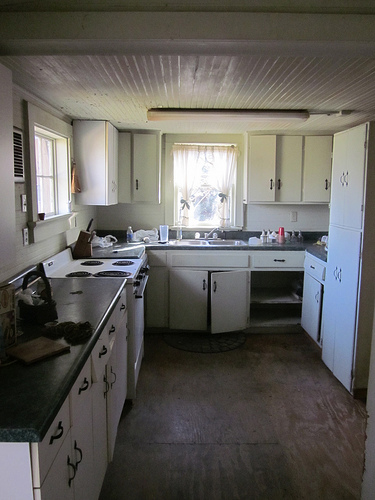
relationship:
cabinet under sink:
[209, 269, 248, 335] [163, 236, 246, 249]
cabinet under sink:
[168, 266, 209, 332] [163, 236, 246, 249]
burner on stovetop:
[77, 257, 103, 267] [44, 245, 145, 281]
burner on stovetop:
[111, 257, 134, 267] [44, 245, 145, 281]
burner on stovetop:
[63, 270, 89, 278] [44, 245, 145, 281]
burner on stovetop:
[95, 270, 130, 278] [44, 245, 145, 281]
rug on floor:
[155, 334, 247, 359] [98, 327, 374, 498]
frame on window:
[159, 135, 241, 230] [176, 143, 231, 227]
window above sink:
[176, 143, 231, 227] [170, 237, 247, 248]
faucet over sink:
[202, 225, 226, 239] [208, 238, 237, 249]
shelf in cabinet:
[252, 289, 303, 311] [249, 264, 305, 327]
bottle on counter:
[126, 226, 133, 243] [88, 234, 147, 259]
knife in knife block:
[85, 216, 93, 232] [73, 229, 95, 257]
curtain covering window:
[170, 144, 240, 229] [169, 138, 242, 232]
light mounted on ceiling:
[145, 107, 310, 126] [20, 57, 364, 139]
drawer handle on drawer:
[274, 258, 286, 263] [252, 248, 303, 269]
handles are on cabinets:
[267, 177, 285, 192] [243, 130, 341, 207]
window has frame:
[35, 124, 65, 216] [21, 97, 76, 141]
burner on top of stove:
[65, 270, 90, 278] [42, 244, 149, 406]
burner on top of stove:
[81, 260, 103, 266] [42, 244, 149, 406]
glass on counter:
[158, 222, 170, 242] [117, 236, 271, 250]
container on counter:
[275, 225, 286, 245] [237, 237, 310, 251]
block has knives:
[73, 229, 93, 257] [83, 217, 97, 248]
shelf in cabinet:
[252, 289, 303, 304] [249, 264, 305, 327]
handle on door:
[210, 280, 219, 293] [209, 265, 248, 333]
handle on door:
[201, 275, 207, 290] [164, 263, 211, 332]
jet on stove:
[112, 256, 135, 271] [70, 247, 143, 289]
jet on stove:
[76, 254, 105, 268] [66, 248, 151, 303]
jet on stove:
[89, 266, 127, 290] [66, 257, 157, 322]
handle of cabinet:
[202, 279, 206, 291] [166, 269, 253, 349]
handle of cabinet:
[213, 280, 217, 293] [166, 269, 253, 349]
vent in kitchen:
[10, 130, 23, 184] [9, 72, 374, 430]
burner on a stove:
[94, 266, 125, 285] [53, 236, 152, 373]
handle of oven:
[132, 272, 153, 308] [132, 258, 156, 373]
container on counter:
[278, 226, 285, 244] [233, 243, 316, 264]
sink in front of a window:
[163, 236, 246, 249] [164, 142, 245, 226]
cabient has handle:
[42, 437, 80, 499] [63, 452, 80, 489]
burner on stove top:
[95, 270, 130, 278] [38, 244, 154, 404]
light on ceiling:
[149, 104, 310, 127] [1, 2, 367, 135]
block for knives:
[72, 227, 97, 261] [84, 216, 95, 238]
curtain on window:
[170, 141, 236, 226] [160, 130, 245, 231]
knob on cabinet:
[329, 266, 344, 284] [318, 119, 372, 395]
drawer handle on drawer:
[274, 258, 286, 263] [250, 250, 305, 270]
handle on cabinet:
[67, 454, 84, 490] [39, 455, 91, 484]